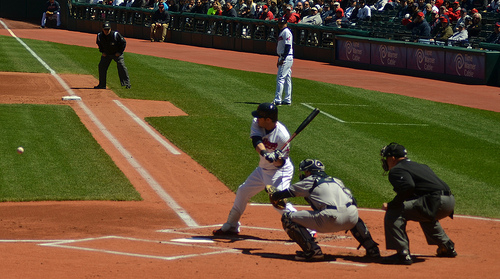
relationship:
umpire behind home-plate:
[380, 142, 457, 265] [168, 236, 216, 244]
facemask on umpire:
[381, 143, 390, 173] [380, 142, 457, 265]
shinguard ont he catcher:
[280, 211, 313, 259] [266, 157, 382, 260]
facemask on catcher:
[297, 159, 308, 183] [266, 157, 382, 260]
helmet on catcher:
[303, 159, 328, 182] [266, 157, 382, 260]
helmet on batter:
[252, 102, 279, 122] [211, 101, 294, 236]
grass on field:
[1, 104, 142, 202] [1, 18, 497, 278]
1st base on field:
[61, 94, 82, 103] [1, 18, 497, 278]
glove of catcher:
[263, 183, 287, 211] [266, 157, 382, 260]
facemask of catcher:
[297, 159, 308, 183] [266, 157, 382, 260]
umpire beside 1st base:
[96, 20, 133, 88] [61, 94, 82, 103]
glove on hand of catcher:
[263, 183, 287, 211] [266, 157, 382, 260]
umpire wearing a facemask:
[380, 142, 457, 265] [381, 143, 390, 173]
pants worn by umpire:
[384, 191, 455, 250] [380, 142, 457, 265]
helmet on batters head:
[252, 102, 279, 122] [258, 103, 280, 132]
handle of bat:
[278, 132, 296, 150] [282, 106, 321, 150]